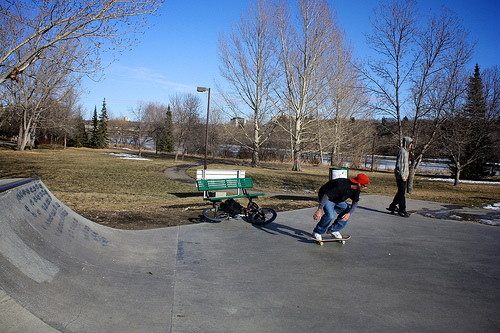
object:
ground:
[0, 169, 499, 332]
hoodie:
[393, 135, 415, 180]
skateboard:
[306, 233, 353, 246]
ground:
[3, 156, 477, 224]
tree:
[155, 102, 176, 153]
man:
[310, 172, 372, 241]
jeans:
[312, 198, 354, 235]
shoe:
[329, 230, 343, 239]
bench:
[195, 176, 265, 208]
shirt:
[316, 177, 361, 215]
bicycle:
[200, 188, 277, 226]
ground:
[387, 259, 497, 328]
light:
[195, 86, 211, 168]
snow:
[427, 170, 499, 185]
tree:
[0, 0, 167, 150]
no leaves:
[420, 6, 456, 52]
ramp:
[0, 178, 499, 332]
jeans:
[388, 173, 409, 214]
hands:
[340, 213, 352, 223]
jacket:
[317, 177, 361, 216]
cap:
[348, 173, 372, 184]